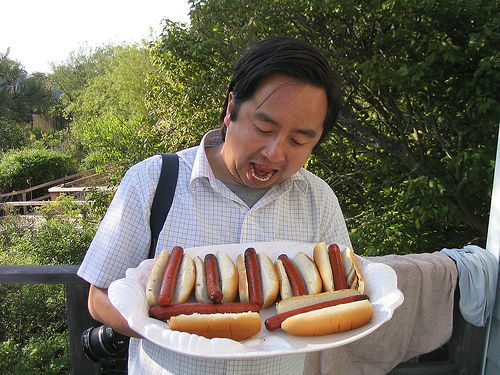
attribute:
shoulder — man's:
[141, 144, 193, 254]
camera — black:
[89, 125, 199, 370]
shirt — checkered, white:
[192, 193, 226, 225]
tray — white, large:
[81, 243, 441, 361]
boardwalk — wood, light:
[2, 160, 129, 222]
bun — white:
[280, 287, 372, 338]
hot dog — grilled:
[157, 246, 184, 305]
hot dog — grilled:
[203, 249, 224, 304]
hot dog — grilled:
[245, 245, 267, 310]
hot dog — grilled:
[279, 251, 307, 299]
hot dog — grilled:
[325, 244, 350, 291]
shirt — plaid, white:
[75, 126, 353, 374]